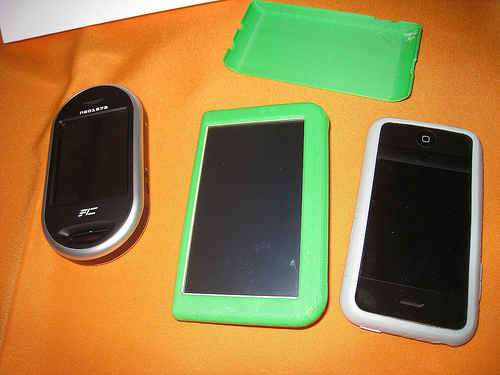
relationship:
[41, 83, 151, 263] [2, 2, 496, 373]
phone on top of cloth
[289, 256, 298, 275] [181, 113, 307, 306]
fingerprint on top of screen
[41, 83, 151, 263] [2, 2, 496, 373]
phone sitting on cloth